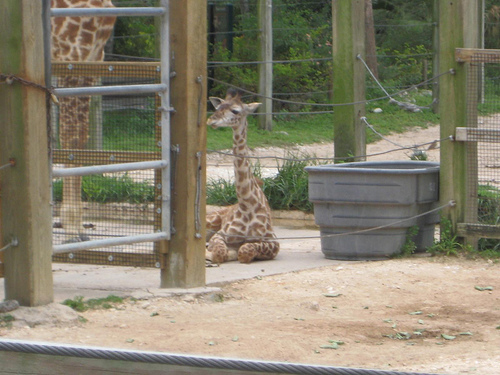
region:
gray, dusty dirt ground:
[0, 259, 499, 374]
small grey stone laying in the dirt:
[322, 288, 347, 304]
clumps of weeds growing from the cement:
[62, 288, 142, 316]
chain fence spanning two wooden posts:
[203, 197, 463, 253]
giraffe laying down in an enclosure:
[187, 94, 292, 285]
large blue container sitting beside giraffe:
[303, 154, 448, 261]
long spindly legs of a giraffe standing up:
[54, 55, 107, 246]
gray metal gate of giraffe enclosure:
[43, 0, 175, 252]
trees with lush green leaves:
[212, 6, 434, 86]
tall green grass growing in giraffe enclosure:
[47, 145, 331, 211]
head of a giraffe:
[190, 68, 258, 141]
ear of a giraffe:
[208, 95, 268, 116]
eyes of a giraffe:
[227, 108, 242, 116]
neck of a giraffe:
[230, 139, 264, 208]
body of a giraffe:
[183, 191, 277, 251]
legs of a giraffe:
[204, 235, 285, 263]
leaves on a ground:
[117, 278, 482, 363]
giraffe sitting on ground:
[141, 86, 304, 269]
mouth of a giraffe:
[207, 112, 225, 131]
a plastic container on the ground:
[300, 142, 440, 257]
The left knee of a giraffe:
[241, 250, 246, 257]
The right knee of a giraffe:
[215, 251, 222, 260]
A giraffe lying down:
[236, 219, 262, 234]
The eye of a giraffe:
[232, 110, 237, 114]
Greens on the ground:
[396, 333, 408, 338]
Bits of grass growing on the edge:
[70, 301, 86, 305]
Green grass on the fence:
[283, 167, 300, 205]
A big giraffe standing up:
[55, 23, 90, 58]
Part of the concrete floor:
[223, 264, 241, 274]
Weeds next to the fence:
[443, 237, 452, 252]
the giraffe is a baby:
[177, 62, 306, 295]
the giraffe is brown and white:
[169, 56, 302, 281]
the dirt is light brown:
[274, 274, 469, 355]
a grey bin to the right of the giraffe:
[302, 128, 444, 266]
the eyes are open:
[201, 98, 246, 120]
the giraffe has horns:
[214, 73, 246, 108]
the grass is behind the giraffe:
[257, 140, 309, 223]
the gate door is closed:
[22, 0, 182, 270]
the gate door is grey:
[25, 21, 183, 255]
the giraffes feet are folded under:
[191, 224, 274, 271]